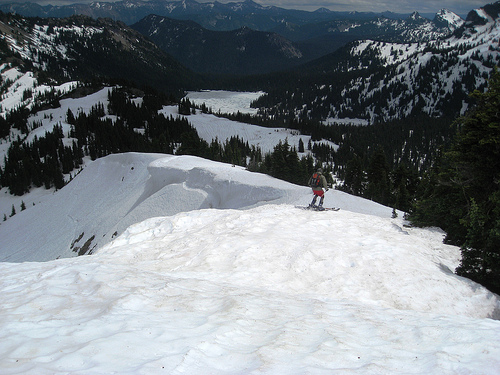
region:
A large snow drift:
[109, 149, 263, 204]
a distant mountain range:
[43, 0, 436, 78]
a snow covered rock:
[61, 225, 142, 262]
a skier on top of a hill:
[293, 158, 348, 220]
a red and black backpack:
[305, 170, 327, 191]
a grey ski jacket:
[305, 163, 332, 195]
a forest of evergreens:
[46, 78, 263, 166]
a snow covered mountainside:
[15, 12, 137, 90]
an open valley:
[151, 63, 276, 122]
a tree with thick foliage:
[366, 141, 391, 202]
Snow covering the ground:
[17, 319, 122, 371]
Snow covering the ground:
[40, 250, 102, 314]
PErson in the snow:
[295, 157, 335, 227]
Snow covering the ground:
[413, 330, 452, 370]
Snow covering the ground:
[339, 330, 377, 370]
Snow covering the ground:
[275, 329, 325, 364]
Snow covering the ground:
[204, 318, 256, 369]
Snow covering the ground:
[164, 241, 217, 283]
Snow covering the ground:
[220, 235, 267, 273]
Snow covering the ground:
[285, 241, 339, 290]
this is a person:
[285, 143, 375, 241]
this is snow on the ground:
[197, 290, 240, 335]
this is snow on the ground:
[259, 274, 359, 356]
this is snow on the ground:
[127, 266, 208, 339]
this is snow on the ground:
[202, 167, 277, 253]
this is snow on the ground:
[330, 208, 430, 329]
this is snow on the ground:
[22, 260, 130, 368]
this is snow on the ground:
[157, 251, 268, 368]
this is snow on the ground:
[170, 81, 291, 160]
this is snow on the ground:
[42, 81, 124, 146]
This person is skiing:
[281, 150, 354, 216]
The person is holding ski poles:
[291, 162, 338, 219]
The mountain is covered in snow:
[25, 159, 297, 364]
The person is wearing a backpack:
[296, 158, 341, 213]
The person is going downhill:
[291, 150, 348, 223]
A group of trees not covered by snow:
[366, 122, 498, 238]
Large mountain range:
[5, 0, 492, 118]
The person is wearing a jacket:
[294, 160, 346, 217]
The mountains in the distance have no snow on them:
[121, 6, 326, 69]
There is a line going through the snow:
[45, 181, 109, 241]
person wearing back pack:
[298, 165, 344, 215]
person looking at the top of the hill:
[292, 160, 342, 216]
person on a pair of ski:
[292, 159, 349, 219]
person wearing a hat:
[291, 164, 345, 216]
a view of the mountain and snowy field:
[17, 15, 296, 258]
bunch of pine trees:
[365, 125, 497, 229]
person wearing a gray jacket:
[294, 158, 343, 214]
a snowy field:
[90, 279, 385, 373]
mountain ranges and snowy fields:
[136, 10, 336, 122]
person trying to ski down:
[272, 160, 355, 220]